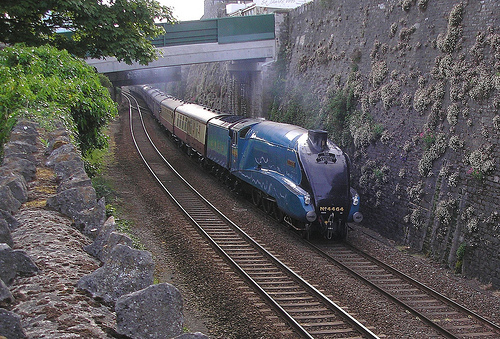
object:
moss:
[414, 69, 445, 125]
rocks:
[262, 0, 499, 281]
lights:
[305, 197, 359, 205]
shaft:
[307, 129, 328, 152]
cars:
[127, 83, 365, 242]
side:
[70, 106, 188, 336]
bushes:
[0, 0, 179, 160]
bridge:
[52, 12, 275, 74]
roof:
[226, 3, 297, 17]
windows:
[90, 34, 120, 52]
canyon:
[0, 0, 499, 339]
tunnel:
[76, 57, 282, 164]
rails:
[113, 82, 498, 339]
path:
[9, 211, 83, 335]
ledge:
[2, 114, 187, 337]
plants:
[283, 1, 500, 86]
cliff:
[290, 0, 500, 293]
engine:
[205, 113, 363, 241]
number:
[320, 207, 344, 212]